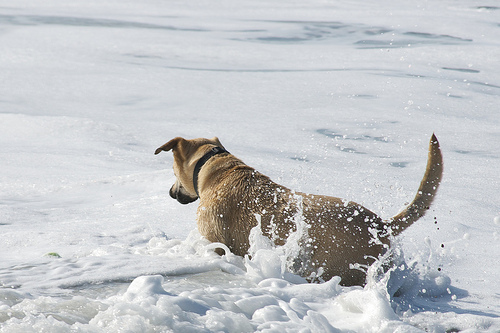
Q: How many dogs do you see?
A: 1.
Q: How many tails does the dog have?
A: One.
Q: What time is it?
A: Daytime.